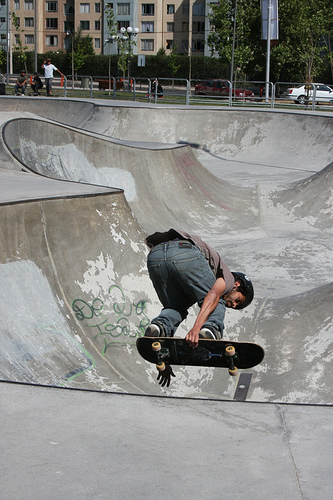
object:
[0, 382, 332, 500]
ramp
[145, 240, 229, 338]
jeans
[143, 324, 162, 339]
shoe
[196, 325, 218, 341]
shoe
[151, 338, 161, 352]
wheel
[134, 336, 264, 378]
skateboard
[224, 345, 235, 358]
wheel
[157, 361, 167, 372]
wheel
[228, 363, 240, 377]
wheel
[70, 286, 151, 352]
grafitti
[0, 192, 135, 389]
ramp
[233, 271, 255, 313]
helmet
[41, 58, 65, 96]
man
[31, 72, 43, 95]
man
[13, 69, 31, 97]
man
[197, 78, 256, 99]
car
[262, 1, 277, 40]
sign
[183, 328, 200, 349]
hand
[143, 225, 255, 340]
man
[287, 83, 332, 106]
car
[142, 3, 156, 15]
window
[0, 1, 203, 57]
building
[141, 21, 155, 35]
window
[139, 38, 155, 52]
window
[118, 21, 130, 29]
window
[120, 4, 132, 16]
window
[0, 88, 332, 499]
skatepark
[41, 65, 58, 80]
shirt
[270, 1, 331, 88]
tree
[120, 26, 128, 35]
lamp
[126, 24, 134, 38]
lamp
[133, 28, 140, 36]
lamp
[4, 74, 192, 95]
road